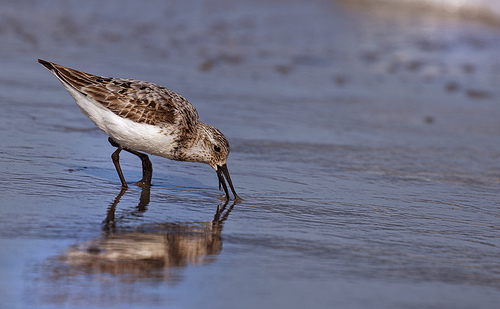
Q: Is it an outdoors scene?
A: Yes, it is outdoors.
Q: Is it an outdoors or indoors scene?
A: It is outdoors.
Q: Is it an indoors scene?
A: No, it is outdoors.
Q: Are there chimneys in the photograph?
A: No, there are no chimneys.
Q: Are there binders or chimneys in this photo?
A: No, there are no chimneys or binders.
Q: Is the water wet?
A: Yes, the water is wet.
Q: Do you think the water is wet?
A: Yes, the water is wet.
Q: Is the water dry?
A: No, the water is wet.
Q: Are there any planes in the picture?
A: No, there are no planes.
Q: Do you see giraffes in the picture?
A: No, there are no giraffes.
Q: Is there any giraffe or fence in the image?
A: No, there are no giraffes or fences.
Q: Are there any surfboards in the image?
A: No, there are no surfboards.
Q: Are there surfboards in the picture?
A: No, there are no surfboards.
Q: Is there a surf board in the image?
A: No, there are no surfboards.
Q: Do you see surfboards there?
A: No, there are no surfboards.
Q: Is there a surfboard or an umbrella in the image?
A: No, there are no surfboards or umbrellas.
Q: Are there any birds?
A: Yes, there is a bird.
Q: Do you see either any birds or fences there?
A: Yes, there is a bird.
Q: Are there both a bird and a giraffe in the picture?
A: No, there is a bird but no giraffes.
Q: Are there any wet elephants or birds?
A: Yes, there is a wet bird.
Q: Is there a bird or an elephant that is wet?
A: Yes, the bird is wet.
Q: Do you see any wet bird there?
A: Yes, there is a wet bird.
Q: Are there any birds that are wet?
A: Yes, there is a bird that is wet.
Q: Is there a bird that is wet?
A: Yes, there is a bird that is wet.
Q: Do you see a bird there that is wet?
A: Yes, there is a bird that is wet.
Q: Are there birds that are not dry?
A: Yes, there is a wet bird.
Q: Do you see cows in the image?
A: No, there are no cows.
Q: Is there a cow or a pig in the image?
A: No, there are no cows or pigs.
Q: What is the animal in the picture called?
A: The animal is a bird.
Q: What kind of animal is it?
A: The animal is a bird.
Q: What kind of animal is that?
A: This is a bird.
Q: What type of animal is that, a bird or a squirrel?
A: This is a bird.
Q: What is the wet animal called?
A: The animal is a bird.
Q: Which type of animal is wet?
A: The animal is a bird.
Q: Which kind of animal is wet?
A: The animal is a bird.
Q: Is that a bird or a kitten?
A: That is a bird.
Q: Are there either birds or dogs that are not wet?
A: No, there is a bird but it is wet.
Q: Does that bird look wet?
A: Yes, the bird is wet.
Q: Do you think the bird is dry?
A: No, the bird is wet.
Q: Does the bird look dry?
A: No, the bird is wet.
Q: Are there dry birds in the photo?
A: No, there is a bird but it is wet.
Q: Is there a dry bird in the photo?
A: No, there is a bird but it is wet.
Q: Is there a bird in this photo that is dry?
A: No, there is a bird but it is wet.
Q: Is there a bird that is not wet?
A: No, there is a bird but it is wet.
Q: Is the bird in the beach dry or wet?
A: The bird is wet.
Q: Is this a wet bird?
A: Yes, this is a wet bird.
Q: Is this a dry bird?
A: No, this is a wet bird.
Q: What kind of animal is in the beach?
A: The animal is a bird.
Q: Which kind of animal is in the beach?
A: The animal is a bird.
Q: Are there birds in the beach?
A: Yes, there is a bird in the beach.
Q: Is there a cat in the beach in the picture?
A: No, there is a bird in the beach.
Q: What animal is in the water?
A: The bird is in the water.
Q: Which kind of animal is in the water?
A: The animal is a bird.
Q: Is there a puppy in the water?
A: No, there is a bird in the water.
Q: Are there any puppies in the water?
A: No, there is a bird in the water.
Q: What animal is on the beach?
A: The bird is on the beach.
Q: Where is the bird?
A: The bird is on the beach.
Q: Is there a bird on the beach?
A: Yes, there is a bird on the beach.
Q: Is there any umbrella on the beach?
A: No, there is a bird on the beach.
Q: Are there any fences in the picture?
A: No, there are no fences.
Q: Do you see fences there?
A: No, there are no fences.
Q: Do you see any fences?
A: No, there are no fences.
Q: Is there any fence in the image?
A: No, there are no fences.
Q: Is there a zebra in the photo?
A: No, there are no zebras.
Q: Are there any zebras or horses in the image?
A: No, there are no zebras or horses.